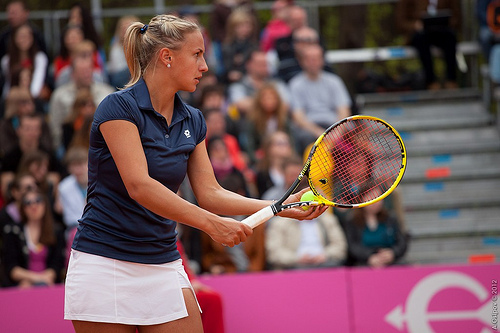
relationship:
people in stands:
[8, 7, 473, 263] [0, 1, 500, 331]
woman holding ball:
[55, 8, 346, 332] [294, 189, 329, 214]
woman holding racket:
[55, 8, 346, 332] [209, 108, 409, 253]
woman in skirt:
[55, 8, 346, 332] [59, 242, 213, 328]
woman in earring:
[55, 8, 346, 332] [163, 59, 170, 69]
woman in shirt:
[55, 8, 346, 332] [68, 86, 201, 269]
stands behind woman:
[0, 1, 500, 331] [55, 8, 346, 332]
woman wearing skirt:
[55, 8, 346, 332] [59, 242, 213, 328]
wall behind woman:
[0, 270, 498, 332] [55, 8, 346, 332]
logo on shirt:
[181, 126, 193, 140] [68, 86, 201, 269]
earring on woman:
[163, 59, 170, 69] [55, 8, 346, 332]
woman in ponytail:
[55, 8, 346, 332] [118, 20, 150, 91]